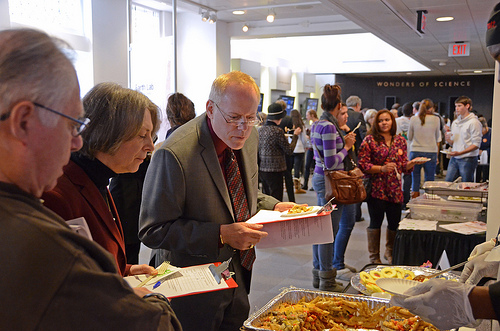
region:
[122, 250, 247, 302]
an orange clipboard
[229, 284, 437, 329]
a silver pan of food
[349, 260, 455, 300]
pineapple circles on the tray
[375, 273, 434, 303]
a white paper plate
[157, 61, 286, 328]
a man looking at the food options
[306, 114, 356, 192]
a woman in a purple and gray sweater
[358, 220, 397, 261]
woman wearing brown boots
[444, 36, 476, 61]
red exit on the ceiling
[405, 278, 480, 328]
man wearing a white glove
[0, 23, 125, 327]
man wearing eye glasses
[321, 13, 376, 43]
part of a ceiling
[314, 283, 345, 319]
part of af ood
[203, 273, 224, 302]
edge of a clipboard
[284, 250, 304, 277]
part of a floor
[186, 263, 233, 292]
part of a paper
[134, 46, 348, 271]
man looking at food buffet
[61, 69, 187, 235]
woman looking at food buffet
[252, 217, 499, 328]
food being served at buffet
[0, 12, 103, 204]
man wearing glasses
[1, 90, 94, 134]
glasses on mans head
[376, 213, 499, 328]
hands of man serving food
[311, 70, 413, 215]
women standing and talking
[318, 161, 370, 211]
brown bag being carried by woman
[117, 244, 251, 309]
clip board being carried by man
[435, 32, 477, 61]
exit sign on ceiling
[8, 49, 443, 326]
people gathered around the trays of food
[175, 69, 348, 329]
an older guy looking at the food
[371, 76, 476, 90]
a wonders of science sign on the wall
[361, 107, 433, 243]
a lady holding a plate of food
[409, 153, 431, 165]
food a woman is holding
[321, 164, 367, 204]
a brown leather bag of the woman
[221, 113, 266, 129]
an eyeglasses a person is wearing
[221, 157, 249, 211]
a tie the person wearing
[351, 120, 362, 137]
a spoon the woman is holding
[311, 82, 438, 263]
people standing next to the table with food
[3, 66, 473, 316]
people standing in room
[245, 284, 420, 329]
food in metal tray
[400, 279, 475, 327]
rubber glove on hand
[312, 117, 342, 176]
striped shirt on woman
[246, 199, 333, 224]
plate of food on clipboard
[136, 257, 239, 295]
paper on orange clipboard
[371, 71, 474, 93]
words on top of wall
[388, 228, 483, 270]
blue cloth on table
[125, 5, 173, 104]
glowing light through window